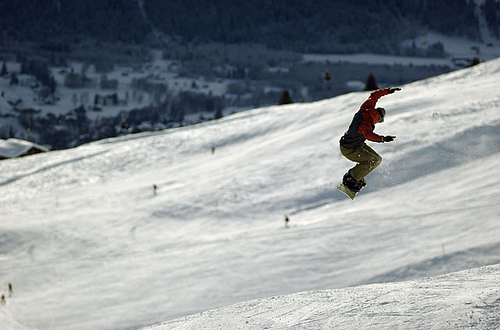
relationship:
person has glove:
[339, 86, 401, 192] [383, 135, 397, 143]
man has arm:
[339, 86, 401, 192] [361, 123, 396, 144]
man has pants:
[339, 86, 401, 192] [341, 143, 382, 182]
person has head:
[339, 86, 401, 192] [373, 107, 386, 124]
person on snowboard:
[339, 86, 401, 192] [336, 173, 368, 200]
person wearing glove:
[339, 86, 401, 192] [383, 135, 397, 143]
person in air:
[339, 86, 401, 192] [2, 2, 499, 284]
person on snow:
[283, 213, 291, 230] [1, 52, 499, 329]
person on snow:
[152, 183, 158, 196] [1, 52, 499, 329]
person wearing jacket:
[339, 86, 401, 192] [341, 87, 389, 149]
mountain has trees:
[1, 1, 499, 153] [0, 0, 499, 68]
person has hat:
[339, 86, 401, 192] [377, 107, 385, 121]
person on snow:
[210, 145, 215, 154] [1, 52, 499, 329]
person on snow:
[7, 282, 15, 299] [1, 52, 499, 329]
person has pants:
[339, 86, 401, 192] [341, 143, 382, 182]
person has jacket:
[339, 86, 401, 192] [341, 87, 389, 149]